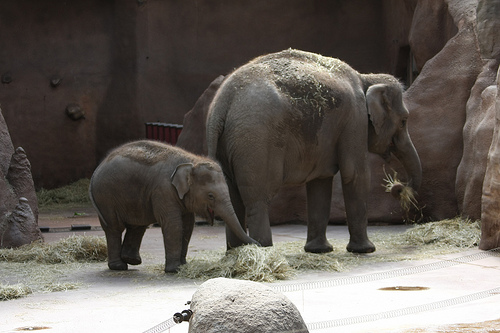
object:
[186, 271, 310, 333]
rock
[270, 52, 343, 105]
grass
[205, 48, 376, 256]
elephant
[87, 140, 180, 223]
baby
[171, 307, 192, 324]
spring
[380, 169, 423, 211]
trunk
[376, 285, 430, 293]
mud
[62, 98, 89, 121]
objects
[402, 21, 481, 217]
rocks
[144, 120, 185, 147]
bars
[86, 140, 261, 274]
elephants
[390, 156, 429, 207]
hay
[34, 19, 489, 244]
exhibit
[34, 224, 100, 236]
ropes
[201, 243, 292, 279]
food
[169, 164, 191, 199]
ear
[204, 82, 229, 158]
tail